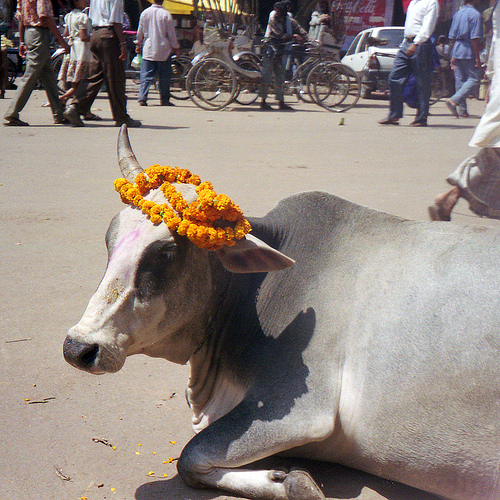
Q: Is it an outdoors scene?
A: Yes, it is outdoors.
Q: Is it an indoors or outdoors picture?
A: It is outdoors.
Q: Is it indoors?
A: No, it is outdoors.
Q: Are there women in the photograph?
A: Yes, there is a woman.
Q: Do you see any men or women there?
A: Yes, there is a woman.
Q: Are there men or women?
A: Yes, there is a woman.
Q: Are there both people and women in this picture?
A: Yes, there are both a woman and people.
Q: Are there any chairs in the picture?
A: No, there are no chairs.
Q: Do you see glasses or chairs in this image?
A: No, there are no chairs or glasses.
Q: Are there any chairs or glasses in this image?
A: No, there are no chairs or glasses.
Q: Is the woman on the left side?
A: Yes, the woman is on the left of the image.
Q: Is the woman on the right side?
A: No, the woman is on the left of the image.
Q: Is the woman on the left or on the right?
A: The woman is on the left of the image.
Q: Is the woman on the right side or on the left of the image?
A: The woman is on the left of the image.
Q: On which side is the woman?
A: The woman is on the left of the image.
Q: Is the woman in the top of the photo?
A: Yes, the woman is in the top of the image.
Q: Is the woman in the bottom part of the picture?
A: No, the woman is in the top of the image.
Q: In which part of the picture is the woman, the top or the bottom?
A: The woman is in the top of the image.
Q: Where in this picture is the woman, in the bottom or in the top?
A: The woman is in the top of the image.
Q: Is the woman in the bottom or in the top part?
A: The woman is in the top of the image.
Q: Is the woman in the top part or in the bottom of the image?
A: The woman is in the top of the image.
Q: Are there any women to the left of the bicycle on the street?
A: Yes, there is a woman to the left of the bicycle.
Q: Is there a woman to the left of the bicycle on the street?
A: Yes, there is a woman to the left of the bicycle.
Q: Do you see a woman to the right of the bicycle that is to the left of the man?
A: No, the woman is to the left of the bicycle.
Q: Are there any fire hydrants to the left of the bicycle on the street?
A: No, there is a woman to the left of the bicycle.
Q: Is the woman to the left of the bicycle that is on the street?
A: Yes, the woman is to the left of the bicycle.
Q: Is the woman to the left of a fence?
A: No, the woman is to the left of the bicycle.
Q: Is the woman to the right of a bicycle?
A: No, the woman is to the left of a bicycle.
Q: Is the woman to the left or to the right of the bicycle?
A: The woman is to the left of the bicycle.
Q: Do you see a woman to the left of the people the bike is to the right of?
A: Yes, there is a woman to the left of the people.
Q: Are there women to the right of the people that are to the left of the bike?
A: No, the woman is to the left of the people.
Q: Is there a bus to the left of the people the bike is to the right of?
A: No, there is a woman to the left of the people.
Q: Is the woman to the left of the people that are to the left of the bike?
A: Yes, the woman is to the left of the people.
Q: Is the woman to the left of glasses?
A: No, the woman is to the left of the people.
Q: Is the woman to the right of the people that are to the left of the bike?
A: No, the woman is to the left of the people.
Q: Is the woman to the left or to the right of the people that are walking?
A: The woman is to the left of the people.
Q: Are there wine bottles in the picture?
A: No, there are no wine bottles.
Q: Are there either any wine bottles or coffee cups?
A: No, there are no wine bottles or coffee cups.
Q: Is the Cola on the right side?
A: Yes, the Cola is on the right of the image.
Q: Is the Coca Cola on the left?
A: No, the Coca Cola is on the right of the image.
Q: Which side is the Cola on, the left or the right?
A: The Cola is on the right of the image.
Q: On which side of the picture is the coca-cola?
A: The coca-cola is on the right of the image.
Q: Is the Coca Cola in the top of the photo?
A: Yes, the Coca Cola is in the top of the image.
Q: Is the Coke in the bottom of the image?
A: No, the Coke is in the top of the image.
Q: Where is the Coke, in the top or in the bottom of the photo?
A: The Coke is in the top of the image.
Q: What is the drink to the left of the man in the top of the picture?
A: The drink is Coke.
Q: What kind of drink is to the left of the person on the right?
A: The drink is Coke.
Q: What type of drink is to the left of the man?
A: The drink is Coke.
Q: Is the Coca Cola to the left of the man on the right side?
A: Yes, the Coca Cola is to the left of the man.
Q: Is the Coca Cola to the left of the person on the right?
A: Yes, the Coca Cola is to the left of the man.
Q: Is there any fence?
A: No, there are no fences.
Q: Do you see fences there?
A: No, there are no fences.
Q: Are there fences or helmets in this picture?
A: No, there are no fences or helmets.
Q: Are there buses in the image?
A: No, there are no buses.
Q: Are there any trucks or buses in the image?
A: No, there are no buses or trucks.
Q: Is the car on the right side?
A: Yes, the car is on the right of the image.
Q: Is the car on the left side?
A: No, the car is on the right of the image.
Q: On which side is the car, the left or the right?
A: The car is on the right of the image.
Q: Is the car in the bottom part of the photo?
A: No, the car is in the top of the image.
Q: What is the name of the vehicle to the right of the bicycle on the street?
A: The vehicle is a car.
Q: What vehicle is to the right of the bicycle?
A: The vehicle is a car.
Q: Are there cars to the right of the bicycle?
A: Yes, there is a car to the right of the bicycle.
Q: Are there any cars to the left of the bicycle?
A: No, the car is to the right of the bicycle.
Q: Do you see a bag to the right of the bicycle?
A: No, there is a car to the right of the bicycle.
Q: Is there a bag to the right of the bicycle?
A: No, there is a car to the right of the bicycle.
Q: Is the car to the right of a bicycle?
A: Yes, the car is to the right of a bicycle.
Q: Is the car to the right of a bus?
A: No, the car is to the right of a bicycle.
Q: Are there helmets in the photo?
A: No, there are no helmets.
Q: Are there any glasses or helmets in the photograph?
A: No, there are no helmets or glasses.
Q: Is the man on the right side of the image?
A: Yes, the man is on the right of the image.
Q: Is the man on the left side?
A: No, the man is on the right of the image.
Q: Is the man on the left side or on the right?
A: The man is on the right of the image.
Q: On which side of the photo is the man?
A: The man is on the right of the image.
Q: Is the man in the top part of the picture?
A: Yes, the man is in the top of the image.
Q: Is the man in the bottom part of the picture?
A: No, the man is in the top of the image.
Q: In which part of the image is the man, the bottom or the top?
A: The man is in the top of the image.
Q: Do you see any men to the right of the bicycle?
A: Yes, there is a man to the right of the bicycle.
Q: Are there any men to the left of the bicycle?
A: No, the man is to the right of the bicycle.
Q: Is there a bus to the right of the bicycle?
A: No, there is a man to the right of the bicycle.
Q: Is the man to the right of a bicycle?
A: Yes, the man is to the right of a bicycle.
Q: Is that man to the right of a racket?
A: No, the man is to the right of a bicycle.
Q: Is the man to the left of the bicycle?
A: No, the man is to the right of the bicycle.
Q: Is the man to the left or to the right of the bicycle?
A: The man is to the right of the bicycle.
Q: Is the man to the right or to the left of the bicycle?
A: The man is to the right of the bicycle.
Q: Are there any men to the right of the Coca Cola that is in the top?
A: Yes, there is a man to the right of the Coke.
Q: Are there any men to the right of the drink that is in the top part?
A: Yes, there is a man to the right of the Coke.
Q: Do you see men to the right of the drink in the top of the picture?
A: Yes, there is a man to the right of the Coke.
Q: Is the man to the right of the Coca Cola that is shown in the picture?
A: Yes, the man is to the right of the Coca Cola.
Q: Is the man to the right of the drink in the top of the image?
A: Yes, the man is to the right of the Coca Cola.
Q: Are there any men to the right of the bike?
A: Yes, there is a man to the right of the bike.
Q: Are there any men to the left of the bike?
A: No, the man is to the right of the bike.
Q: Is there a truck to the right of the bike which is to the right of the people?
A: No, there is a man to the right of the bike.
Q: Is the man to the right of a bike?
A: Yes, the man is to the right of a bike.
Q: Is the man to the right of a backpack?
A: No, the man is to the right of a bike.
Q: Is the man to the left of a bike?
A: No, the man is to the right of a bike.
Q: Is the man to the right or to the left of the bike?
A: The man is to the right of the bike.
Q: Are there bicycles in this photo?
A: Yes, there is a bicycle.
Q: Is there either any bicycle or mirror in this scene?
A: Yes, there is a bicycle.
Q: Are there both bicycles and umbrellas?
A: No, there is a bicycle but no umbrellas.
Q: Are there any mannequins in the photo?
A: No, there are no mannequins.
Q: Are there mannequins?
A: No, there are no mannequins.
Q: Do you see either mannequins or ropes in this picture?
A: No, there are no mannequins or ropes.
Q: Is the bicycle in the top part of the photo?
A: Yes, the bicycle is in the top of the image.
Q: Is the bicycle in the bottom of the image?
A: No, the bicycle is in the top of the image.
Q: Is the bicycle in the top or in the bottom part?
A: The bicycle is in the top of the image.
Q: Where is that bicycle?
A: The bicycle is on the street.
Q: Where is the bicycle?
A: The bicycle is on the street.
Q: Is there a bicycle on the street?
A: Yes, there is a bicycle on the street.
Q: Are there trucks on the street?
A: No, there is a bicycle on the street.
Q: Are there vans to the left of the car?
A: No, there is a bicycle to the left of the car.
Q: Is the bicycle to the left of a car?
A: Yes, the bicycle is to the left of a car.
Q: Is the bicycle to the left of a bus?
A: No, the bicycle is to the left of a car.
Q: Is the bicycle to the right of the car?
A: No, the bicycle is to the left of the car.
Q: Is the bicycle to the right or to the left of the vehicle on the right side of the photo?
A: The bicycle is to the left of the car.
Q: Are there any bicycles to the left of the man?
A: Yes, there is a bicycle to the left of the man.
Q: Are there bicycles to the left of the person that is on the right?
A: Yes, there is a bicycle to the left of the man.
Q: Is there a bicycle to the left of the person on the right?
A: Yes, there is a bicycle to the left of the man.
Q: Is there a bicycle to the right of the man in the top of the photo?
A: No, the bicycle is to the left of the man.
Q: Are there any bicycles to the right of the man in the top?
A: No, the bicycle is to the left of the man.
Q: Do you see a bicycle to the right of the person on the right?
A: No, the bicycle is to the left of the man.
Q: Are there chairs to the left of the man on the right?
A: No, there is a bicycle to the left of the man.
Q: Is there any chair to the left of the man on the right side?
A: No, there is a bicycle to the left of the man.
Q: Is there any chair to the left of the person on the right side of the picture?
A: No, there is a bicycle to the left of the man.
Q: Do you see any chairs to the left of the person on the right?
A: No, there is a bicycle to the left of the man.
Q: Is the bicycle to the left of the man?
A: Yes, the bicycle is to the left of the man.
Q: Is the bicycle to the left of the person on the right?
A: Yes, the bicycle is to the left of the man.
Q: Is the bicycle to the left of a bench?
A: No, the bicycle is to the left of the man.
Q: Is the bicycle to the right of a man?
A: No, the bicycle is to the left of a man.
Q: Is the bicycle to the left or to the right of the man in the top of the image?
A: The bicycle is to the left of the man.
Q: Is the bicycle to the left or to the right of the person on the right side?
A: The bicycle is to the left of the man.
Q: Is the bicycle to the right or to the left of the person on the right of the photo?
A: The bicycle is to the left of the man.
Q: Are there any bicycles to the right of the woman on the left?
A: Yes, there is a bicycle to the right of the woman.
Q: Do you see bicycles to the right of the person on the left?
A: Yes, there is a bicycle to the right of the woman.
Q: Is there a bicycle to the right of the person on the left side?
A: Yes, there is a bicycle to the right of the woman.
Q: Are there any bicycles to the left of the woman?
A: No, the bicycle is to the right of the woman.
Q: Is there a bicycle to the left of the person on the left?
A: No, the bicycle is to the right of the woman.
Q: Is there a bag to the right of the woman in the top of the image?
A: No, there is a bicycle to the right of the woman.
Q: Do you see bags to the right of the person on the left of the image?
A: No, there is a bicycle to the right of the woman.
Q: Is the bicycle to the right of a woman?
A: Yes, the bicycle is to the right of a woman.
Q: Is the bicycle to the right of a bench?
A: No, the bicycle is to the right of a woman.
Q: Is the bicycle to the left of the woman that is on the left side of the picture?
A: No, the bicycle is to the right of the woman.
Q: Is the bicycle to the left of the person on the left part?
A: No, the bicycle is to the right of the woman.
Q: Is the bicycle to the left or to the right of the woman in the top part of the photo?
A: The bicycle is to the right of the woman.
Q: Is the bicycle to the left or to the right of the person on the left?
A: The bicycle is to the right of the woman.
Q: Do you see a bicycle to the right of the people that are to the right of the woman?
A: Yes, there is a bicycle to the right of the people.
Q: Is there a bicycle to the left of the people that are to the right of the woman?
A: No, the bicycle is to the right of the people.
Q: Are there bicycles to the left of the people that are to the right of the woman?
A: No, the bicycle is to the right of the people.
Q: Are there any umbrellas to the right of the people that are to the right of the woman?
A: No, there is a bicycle to the right of the people.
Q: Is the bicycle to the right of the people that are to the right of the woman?
A: Yes, the bicycle is to the right of the people.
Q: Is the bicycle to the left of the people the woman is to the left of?
A: No, the bicycle is to the right of the people.